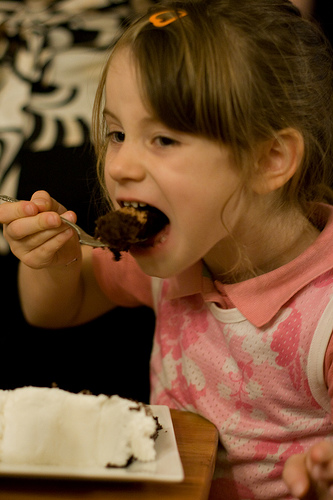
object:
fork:
[0, 190, 114, 254]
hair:
[298, 173, 333, 223]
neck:
[208, 213, 318, 287]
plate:
[0, 402, 188, 486]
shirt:
[68, 212, 331, 498]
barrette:
[146, 7, 194, 29]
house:
[0, 4, 333, 500]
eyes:
[106, 126, 126, 151]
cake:
[93, 202, 151, 247]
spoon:
[1, 190, 108, 250]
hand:
[1, 187, 83, 271]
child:
[0, 0, 331, 499]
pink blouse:
[89, 198, 332, 499]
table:
[2, 388, 217, 497]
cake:
[0, 383, 162, 469]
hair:
[140, 8, 325, 132]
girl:
[3, 4, 332, 494]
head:
[93, 3, 327, 277]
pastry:
[28, 373, 159, 474]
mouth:
[111, 195, 173, 257]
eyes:
[152, 133, 182, 149]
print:
[157, 300, 222, 378]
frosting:
[0, 389, 159, 464]